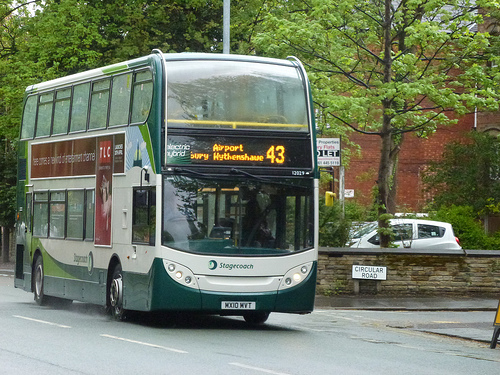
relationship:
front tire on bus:
[106, 262, 127, 320] [12, 49, 318, 320]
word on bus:
[212, 142, 244, 152] [12, 49, 318, 320]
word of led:
[212, 142, 244, 152] [181, 139, 290, 166]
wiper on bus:
[165, 157, 238, 182] [17, 49, 361, 305]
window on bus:
[128, 179, 159, 249] [12, 43, 333, 331]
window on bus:
[126, 65, 156, 126] [12, 49, 318, 320]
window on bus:
[107, 72, 133, 128] [12, 49, 318, 320]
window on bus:
[114, 75, 168, 119] [18, 35, 374, 337]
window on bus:
[34, 89, 54, 140] [12, 49, 318, 320]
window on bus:
[52, 86, 70, 136] [12, 49, 318, 320]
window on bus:
[69, 81, 89, 133] [12, 49, 318, 320]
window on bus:
[88, 79, 108, 131] [12, 49, 318, 320]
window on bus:
[64, 188, 83, 235] [12, 49, 318, 320]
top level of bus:
[68, 58, 198, 120] [23, 26, 330, 333]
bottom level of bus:
[12, 168, 321, 327] [12, 171, 318, 311]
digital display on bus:
[184, 138, 285, 165] [160, 130, 316, 170]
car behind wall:
[338, 213, 463, 255] [316, 247, 498, 294]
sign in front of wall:
[348, 262, 393, 288] [313, 222, 495, 309]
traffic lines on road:
[10, 308, 290, 373] [15, 301, 499, 371]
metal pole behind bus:
[210, 12, 247, 41] [12, 49, 318, 320]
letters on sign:
[320, 147, 339, 157] [313, 137, 343, 169]